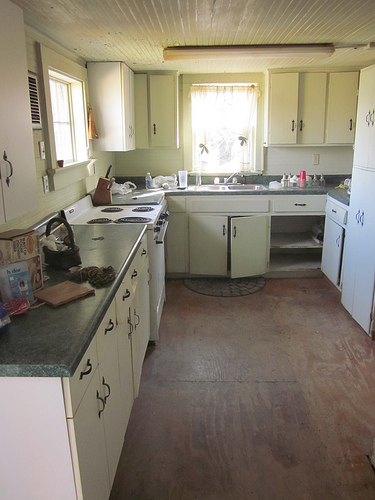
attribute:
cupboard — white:
[265, 67, 300, 148]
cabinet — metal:
[68, 346, 126, 498]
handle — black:
[100, 376, 109, 403]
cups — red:
[294, 167, 306, 191]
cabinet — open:
[270, 205, 320, 274]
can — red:
[1, 295, 29, 317]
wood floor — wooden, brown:
[201, 354, 297, 447]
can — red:
[296, 166, 307, 190]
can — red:
[298, 169, 307, 185]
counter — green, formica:
[9, 315, 88, 355]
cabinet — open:
[161, 212, 343, 279]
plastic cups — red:
[297, 171, 308, 189]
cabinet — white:
[274, 85, 334, 136]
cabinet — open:
[190, 211, 273, 280]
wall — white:
[98, 137, 183, 178]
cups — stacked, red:
[296, 169, 306, 186]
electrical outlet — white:
[40, 172, 51, 192]